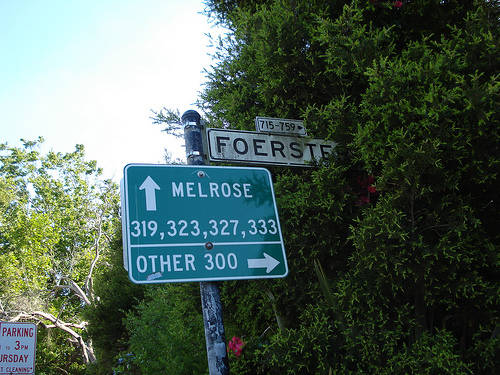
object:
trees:
[116, 2, 497, 374]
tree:
[1, 139, 126, 364]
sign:
[256, 112, 307, 136]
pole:
[181, 109, 229, 374]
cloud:
[34, 43, 162, 138]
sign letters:
[0, 310, 43, 373]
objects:
[361, 174, 381, 197]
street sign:
[204, 119, 339, 164]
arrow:
[138, 178, 160, 213]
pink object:
[227, 334, 243, 358]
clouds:
[80, 49, 155, 154]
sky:
[7, 5, 121, 77]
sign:
[119, 160, 295, 294]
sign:
[206, 107, 357, 172]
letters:
[216, 132, 330, 159]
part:
[460, 189, 480, 207]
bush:
[289, 301, 450, 375]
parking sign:
[0, 322, 36, 371]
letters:
[171, 177, 255, 197]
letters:
[171, 180, 186, 200]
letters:
[185, 181, 195, 198]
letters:
[196, 180, 210, 198]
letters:
[207, 181, 221, 198]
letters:
[219, 182, 233, 199]